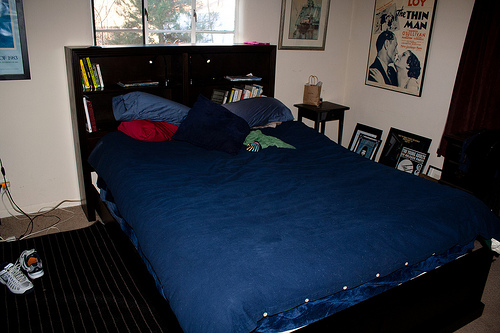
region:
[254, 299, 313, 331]
white studs in bed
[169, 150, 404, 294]
solid blue bed spread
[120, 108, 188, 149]
small red pillow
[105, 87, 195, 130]
crumpled blue pillow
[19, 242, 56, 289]
red socks in white sneaker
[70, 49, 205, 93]
books in bed head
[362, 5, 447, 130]
large movie poster on wall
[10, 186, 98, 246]
long black electrical cords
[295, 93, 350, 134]
small black night table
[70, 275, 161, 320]
black floor with thin lines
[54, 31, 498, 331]
Bed in a bedroom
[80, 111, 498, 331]
Comforter of bed is blue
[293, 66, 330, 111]
Bag on night table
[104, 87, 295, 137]
Long blue pillow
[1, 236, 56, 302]
Tennis shoes are white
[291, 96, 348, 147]
Night table on the corner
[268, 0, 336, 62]
Picture on the wall of bedroom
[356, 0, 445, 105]
Poster on a movie hold in the wall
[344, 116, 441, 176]
Pictures leaning on the wall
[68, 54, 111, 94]
Books on a bed shelf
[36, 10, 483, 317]
bed in a small bedroom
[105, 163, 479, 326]
royal blue coverlet on the bed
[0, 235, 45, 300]
white athletic shoes on floor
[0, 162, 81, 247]
electrical cords for devices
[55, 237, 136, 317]
small black striped rub on top of carpeting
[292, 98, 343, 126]
small wooden square night stand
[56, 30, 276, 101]
head board of bed has shelves built in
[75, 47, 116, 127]
books are on the headboard shelves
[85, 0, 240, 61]
the bed is places in front of a window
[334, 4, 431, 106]
a black and white poster of 'The Thin Man' is on the wall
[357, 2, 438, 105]
Thin Man poster on wall.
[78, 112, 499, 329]
Blue duvet cover on bed.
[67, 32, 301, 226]
Headboard has shelves for books.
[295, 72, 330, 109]
Paper bag on table.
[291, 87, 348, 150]
Square table beside bed.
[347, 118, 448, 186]
Framed pictures leaning against wall.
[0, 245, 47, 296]
Tennis shoes on floor.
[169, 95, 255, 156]
Throw pillow is navy blue.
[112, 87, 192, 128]
Blue pillow case on pillow.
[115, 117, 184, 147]
Red pillow case on pillow.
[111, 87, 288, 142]
pillows at head of bed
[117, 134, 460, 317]
blue comforter on bed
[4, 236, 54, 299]
pair of sneakers on floor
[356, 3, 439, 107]
poster of old movie on wall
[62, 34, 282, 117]
headboard with shelves of books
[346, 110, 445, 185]
framed pictures propped against wall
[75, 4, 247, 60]
wall behind wood shelf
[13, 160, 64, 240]
wires plugged into wall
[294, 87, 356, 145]
end table on side of bed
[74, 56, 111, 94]
tilted books in shelf